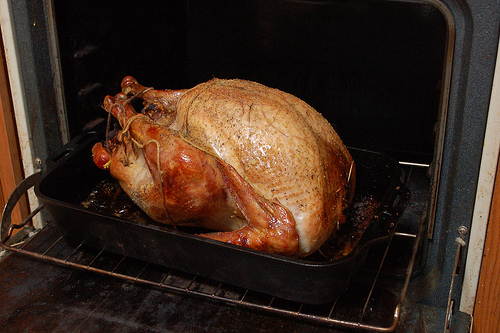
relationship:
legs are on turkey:
[100, 92, 225, 224] [92, 74, 360, 259]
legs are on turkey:
[117, 75, 190, 120] [92, 74, 360, 259]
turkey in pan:
[92, 74, 360, 259] [31, 149, 405, 294]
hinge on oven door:
[1, 166, 43, 241] [2, 226, 474, 330]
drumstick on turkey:
[99, 91, 225, 226] [92, 74, 360, 259]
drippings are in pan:
[352, 192, 369, 250] [23, 121, 415, 302]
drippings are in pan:
[83, 172, 125, 212] [23, 121, 415, 302]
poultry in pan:
[88, 72, 360, 253] [23, 121, 415, 302]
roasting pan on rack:
[28, 127, 418, 313] [3, 212, 452, 286]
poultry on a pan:
[88, 72, 360, 253] [23, 121, 415, 302]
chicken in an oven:
[73, 38, 368, 293] [43, 30, 462, 313]